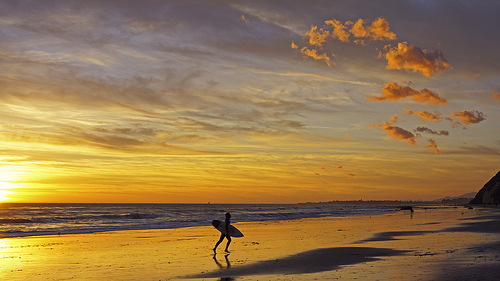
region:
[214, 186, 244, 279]
a person holding a surf board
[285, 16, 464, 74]
white clouds in a blue sky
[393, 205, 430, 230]
someone walking on a beach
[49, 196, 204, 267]
the ocean and sandy beach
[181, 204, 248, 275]
a person holding a surf board walking on a beac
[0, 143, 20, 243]
the sun going down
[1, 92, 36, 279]
a sunset over the ocean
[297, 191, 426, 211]
a row of trees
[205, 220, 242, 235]
a surf board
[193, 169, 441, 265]
two people walking on the beach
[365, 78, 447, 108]
an orange and brown fluffy cloud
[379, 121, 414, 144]
an orange and brown fluffy cloud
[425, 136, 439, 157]
an orange and brown fluffy cloud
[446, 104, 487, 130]
an orange and brown fluffy cloud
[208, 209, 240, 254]
a person walking on the beach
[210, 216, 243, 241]
a long surfboard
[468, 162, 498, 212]
a hill in the distance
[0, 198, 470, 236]
the blue ocean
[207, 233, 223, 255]
the leg of a person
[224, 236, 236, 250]
the leg of a person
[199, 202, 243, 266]
person walking on the beach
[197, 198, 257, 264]
person carrying a surfboard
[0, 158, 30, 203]
sun is setting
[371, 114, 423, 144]
puffy clouds that are tinted orange by the sun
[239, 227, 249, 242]
pointy edge of the surfboard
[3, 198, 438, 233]
body of water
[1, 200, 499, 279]
beach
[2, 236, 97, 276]
sand that is tinted orange from the sun's light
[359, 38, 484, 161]
cloud formation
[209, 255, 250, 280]
shadow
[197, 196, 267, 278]
surfer on a wet beach.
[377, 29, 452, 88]
an orange cloud in a sky.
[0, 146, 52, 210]
the sun setting into the ocean.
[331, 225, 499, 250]
a wave on a beach.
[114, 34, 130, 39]
a section of blue sky.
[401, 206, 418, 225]
a person standing on a beach.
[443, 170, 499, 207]
a hill on a beach.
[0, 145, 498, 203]
an orange sunset over the ocean.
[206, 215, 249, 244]
a person holding a surfboard.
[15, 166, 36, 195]
a section of corona.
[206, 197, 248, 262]
person with surf board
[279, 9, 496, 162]
orange clouds from rising or setting sun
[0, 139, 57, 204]
rising or setting sun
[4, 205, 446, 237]
twilight darkened ocean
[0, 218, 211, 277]
twilight colored beach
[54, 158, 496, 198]
orange colored clouds on horizon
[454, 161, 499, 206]
hills in the distance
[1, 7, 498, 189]
multicolored sky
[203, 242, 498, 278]
shadowed areas on beach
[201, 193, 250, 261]
person running on beach